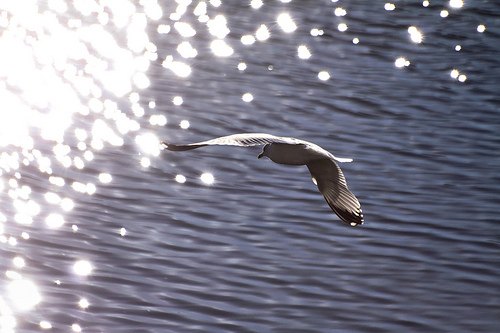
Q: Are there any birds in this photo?
A: Yes, there is a bird.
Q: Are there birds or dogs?
A: Yes, there is a bird.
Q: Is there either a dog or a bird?
A: Yes, there is a bird.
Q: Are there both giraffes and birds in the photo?
A: No, there is a bird but no giraffes.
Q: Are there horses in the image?
A: No, there are no horses.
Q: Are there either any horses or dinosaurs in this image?
A: No, there are no horses or dinosaurs.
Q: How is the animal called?
A: The animal is a bird.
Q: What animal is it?
A: The animal is a bird.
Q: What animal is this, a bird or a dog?
A: This is a bird.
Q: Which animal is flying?
A: The animal is a bird.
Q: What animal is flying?
A: The animal is a bird.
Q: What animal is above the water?
A: The animal is a bird.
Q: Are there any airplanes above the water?
A: No, there is a bird above the water.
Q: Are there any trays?
A: No, there are no trays.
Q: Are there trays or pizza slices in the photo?
A: No, there are no trays or pizza slices.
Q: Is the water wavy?
A: Yes, the water is wavy.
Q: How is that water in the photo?
A: The water is wavy.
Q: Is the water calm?
A: No, the water is wavy.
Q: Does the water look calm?
A: No, the water is wavy.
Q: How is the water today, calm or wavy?
A: The water is wavy.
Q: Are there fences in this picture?
A: No, there are no fences.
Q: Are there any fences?
A: No, there are no fences.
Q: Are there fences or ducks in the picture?
A: No, there are no fences or ducks.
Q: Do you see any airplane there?
A: No, there are no airplanes.